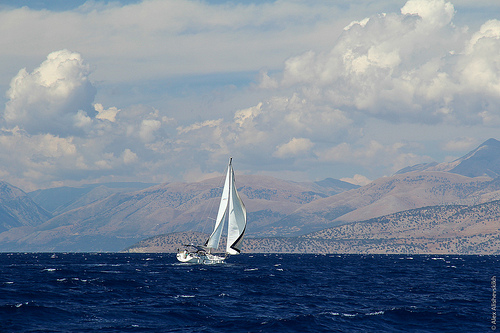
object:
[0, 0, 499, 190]
sky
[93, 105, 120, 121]
clouds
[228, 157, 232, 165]
metal tip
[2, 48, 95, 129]
clouds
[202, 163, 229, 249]
lining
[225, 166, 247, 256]
sail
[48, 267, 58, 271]
white cap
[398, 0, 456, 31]
cloud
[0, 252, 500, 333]
blue water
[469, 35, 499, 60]
clouds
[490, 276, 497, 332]
copyright symbol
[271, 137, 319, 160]
clouds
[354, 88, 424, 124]
clouds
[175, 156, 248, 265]
boat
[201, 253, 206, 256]
people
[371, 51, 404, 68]
clouds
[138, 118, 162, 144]
clouds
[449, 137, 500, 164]
mountains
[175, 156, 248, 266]
sailboat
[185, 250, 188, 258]
people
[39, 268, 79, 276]
wave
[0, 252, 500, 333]
ocean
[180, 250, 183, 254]
person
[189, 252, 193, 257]
person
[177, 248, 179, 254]
person